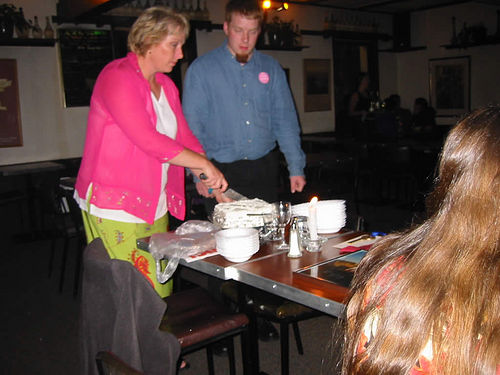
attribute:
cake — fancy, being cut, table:
[207, 179, 283, 236]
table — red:
[226, 254, 309, 307]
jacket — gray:
[372, 100, 432, 132]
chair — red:
[194, 294, 243, 342]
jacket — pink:
[97, 119, 164, 191]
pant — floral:
[108, 226, 149, 258]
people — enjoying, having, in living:
[75, 19, 311, 256]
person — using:
[129, 110, 357, 249]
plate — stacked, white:
[280, 167, 362, 251]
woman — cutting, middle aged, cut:
[44, 54, 245, 276]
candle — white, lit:
[298, 190, 332, 252]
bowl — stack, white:
[201, 226, 265, 264]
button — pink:
[119, 184, 154, 224]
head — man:
[232, 7, 277, 46]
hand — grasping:
[168, 143, 274, 218]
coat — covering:
[84, 222, 170, 333]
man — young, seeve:
[184, 32, 290, 171]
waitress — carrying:
[404, 117, 496, 231]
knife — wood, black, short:
[187, 173, 264, 219]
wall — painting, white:
[1, 33, 92, 162]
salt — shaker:
[283, 219, 325, 269]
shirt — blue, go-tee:
[231, 105, 273, 123]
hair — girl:
[140, 30, 160, 49]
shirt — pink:
[107, 119, 148, 158]